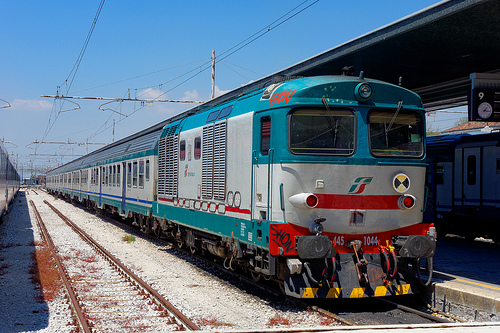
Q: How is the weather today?
A: It is cloudy.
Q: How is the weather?
A: It is cloudy.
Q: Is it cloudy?
A: Yes, it is cloudy.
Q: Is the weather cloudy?
A: Yes, it is cloudy.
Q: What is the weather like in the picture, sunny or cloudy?
A: It is cloudy.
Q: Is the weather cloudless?
A: No, it is cloudy.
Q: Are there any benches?
A: No, there are no benches.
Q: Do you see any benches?
A: No, there are no benches.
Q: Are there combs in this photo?
A: No, there are no combs.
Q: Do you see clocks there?
A: Yes, there is a clock.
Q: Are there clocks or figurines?
A: Yes, there is a clock.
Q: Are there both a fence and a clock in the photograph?
A: No, there is a clock but no fences.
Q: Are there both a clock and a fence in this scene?
A: No, there is a clock but no fences.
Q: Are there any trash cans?
A: No, there are no trash cans.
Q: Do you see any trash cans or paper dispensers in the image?
A: No, there are no trash cans or paper dispensers.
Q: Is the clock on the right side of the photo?
A: Yes, the clock is on the right of the image.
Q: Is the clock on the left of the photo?
A: No, the clock is on the right of the image.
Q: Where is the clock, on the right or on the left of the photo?
A: The clock is on the right of the image.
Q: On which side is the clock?
A: The clock is on the right of the image.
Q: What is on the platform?
A: The clock is on the platform.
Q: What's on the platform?
A: The clock is on the platform.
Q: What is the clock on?
A: The clock is on the platform.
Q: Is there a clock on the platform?
A: Yes, there is a clock on the platform.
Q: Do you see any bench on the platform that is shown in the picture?
A: No, there is a clock on the platform.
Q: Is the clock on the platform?
A: Yes, the clock is on the platform.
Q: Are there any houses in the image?
A: No, there are no houses.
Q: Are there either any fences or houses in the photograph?
A: No, there are no houses or fences.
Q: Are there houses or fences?
A: No, there are no houses or fences.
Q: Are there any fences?
A: No, there are no fences.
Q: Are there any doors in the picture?
A: Yes, there is a door.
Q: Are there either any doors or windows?
A: Yes, there is a door.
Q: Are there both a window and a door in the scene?
A: Yes, there are both a door and a window.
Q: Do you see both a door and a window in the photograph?
A: Yes, there are both a door and a window.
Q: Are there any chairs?
A: No, there are no chairs.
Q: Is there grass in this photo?
A: Yes, there is grass.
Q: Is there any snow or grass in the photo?
A: Yes, there is grass.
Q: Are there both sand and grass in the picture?
A: No, there is grass but no sand.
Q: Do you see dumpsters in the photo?
A: No, there are no dumpsters.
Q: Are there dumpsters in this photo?
A: No, there are no dumpsters.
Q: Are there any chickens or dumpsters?
A: No, there are no dumpsters or chickens.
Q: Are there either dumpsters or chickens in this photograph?
A: No, there are no dumpsters or chickens.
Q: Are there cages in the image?
A: No, there are no cages.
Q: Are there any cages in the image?
A: No, there are no cages.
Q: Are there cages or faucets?
A: No, there are no cages or faucets.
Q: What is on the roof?
A: The graffiti is on the roof.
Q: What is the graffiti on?
A: The graffiti is on the roof.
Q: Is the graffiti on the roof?
A: Yes, the graffiti is on the roof.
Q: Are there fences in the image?
A: No, there are no fences.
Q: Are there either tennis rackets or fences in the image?
A: No, there are no fences or tennis rackets.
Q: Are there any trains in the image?
A: Yes, there are trains.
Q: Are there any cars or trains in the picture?
A: Yes, there are trains.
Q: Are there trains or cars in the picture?
A: Yes, there are trains.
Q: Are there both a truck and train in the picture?
A: No, there are trains but no trucks.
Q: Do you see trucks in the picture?
A: No, there are no trucks.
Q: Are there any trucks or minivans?
A: No, there are no trucks or minivans.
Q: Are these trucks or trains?
A: These are trains.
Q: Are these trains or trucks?
A: These are trains.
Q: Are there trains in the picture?
A: Yes, there is a train.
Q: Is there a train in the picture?
A: Yes, there is a train.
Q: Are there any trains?
A: Yes, there is a train.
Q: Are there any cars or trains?
A: Yes, there is a train.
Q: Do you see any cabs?
A: No, there are no cabs.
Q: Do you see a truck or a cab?
A: No, there are no taxis or trucks.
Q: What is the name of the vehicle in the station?
A: The vehicle is a train.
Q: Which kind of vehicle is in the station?
A: The vehicle is a train.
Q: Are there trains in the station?
A: Yes, there is a train in the station.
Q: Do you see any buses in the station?
A: No, there is a train in the station.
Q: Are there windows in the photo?
A: Yes, there are windows.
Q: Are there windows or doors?
A: Yes, there are windows.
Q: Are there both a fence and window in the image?
A: No, there are windows but no fences.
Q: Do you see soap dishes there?
A: No, there are no soap dishes.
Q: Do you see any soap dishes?
A: No, there are no soap dishes.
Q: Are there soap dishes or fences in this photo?
A: No, there are no soap dishes or fences.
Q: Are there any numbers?
A: Yes, there are numbers.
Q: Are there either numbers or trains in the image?
A: Yes, there are numbers.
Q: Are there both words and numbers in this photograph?
A: No, there are numbers but no words.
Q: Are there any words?
A: No, there are no words.